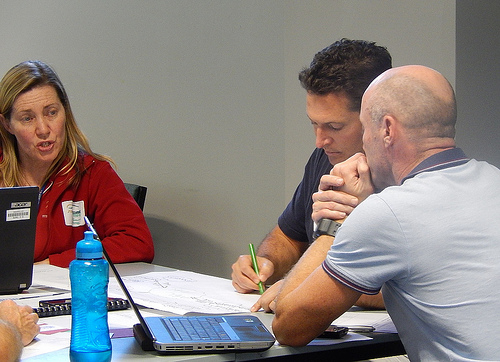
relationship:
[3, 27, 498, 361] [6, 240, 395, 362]
people working at a table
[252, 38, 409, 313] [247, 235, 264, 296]
man holding pen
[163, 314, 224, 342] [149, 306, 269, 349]
keys on keyboard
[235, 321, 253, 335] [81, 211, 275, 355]
touchpad on laptop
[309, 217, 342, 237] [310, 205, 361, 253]
watch on wrist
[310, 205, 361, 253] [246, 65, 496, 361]
wrist of man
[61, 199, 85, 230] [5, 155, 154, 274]
name tag on sweatshirt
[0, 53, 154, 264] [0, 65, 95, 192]
woman with hair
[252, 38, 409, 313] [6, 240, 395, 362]
man sitting at table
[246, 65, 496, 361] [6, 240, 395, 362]
man sitting at table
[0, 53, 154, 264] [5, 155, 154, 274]
woman in sweatshirt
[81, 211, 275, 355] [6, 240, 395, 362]
laptop on a table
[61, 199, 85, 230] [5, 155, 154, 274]
name tag on a sweatshirt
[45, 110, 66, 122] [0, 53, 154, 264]
left eye of woman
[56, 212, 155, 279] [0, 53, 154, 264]
left arm of woman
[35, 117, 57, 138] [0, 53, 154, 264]
nose on woman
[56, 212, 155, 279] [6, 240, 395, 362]
left arm on table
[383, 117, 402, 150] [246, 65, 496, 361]
left ear of man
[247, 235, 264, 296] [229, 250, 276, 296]
pen in hand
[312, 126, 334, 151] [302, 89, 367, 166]
nose on face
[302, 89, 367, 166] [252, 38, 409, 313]
face of man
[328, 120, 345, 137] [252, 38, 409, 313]
left eye of man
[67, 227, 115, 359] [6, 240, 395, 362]
water bottle on table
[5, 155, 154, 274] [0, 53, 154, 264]
sweatshirt of woman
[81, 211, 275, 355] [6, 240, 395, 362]
laptop on table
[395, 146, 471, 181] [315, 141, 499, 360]
collar on shirt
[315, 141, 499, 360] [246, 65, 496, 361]
shirt of man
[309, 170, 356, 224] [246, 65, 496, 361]
right hand of man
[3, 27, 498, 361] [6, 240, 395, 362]
people converse over table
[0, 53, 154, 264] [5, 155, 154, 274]
woman wears sweatshirt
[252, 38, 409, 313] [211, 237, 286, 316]
man taking notes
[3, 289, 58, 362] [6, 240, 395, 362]
arm on table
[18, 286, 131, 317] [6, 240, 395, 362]
spiral notebook on table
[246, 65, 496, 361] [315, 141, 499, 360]
man wearing a shirt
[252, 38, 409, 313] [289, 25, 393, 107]
man has hair